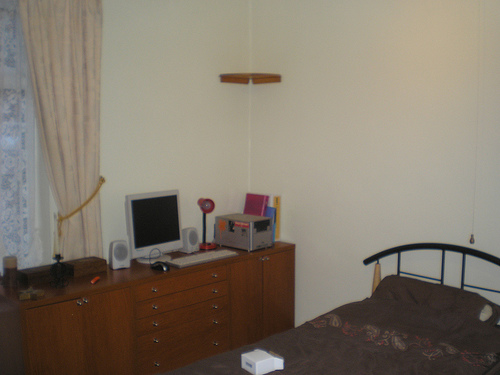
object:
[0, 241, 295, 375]
dresser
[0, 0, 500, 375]
bedroom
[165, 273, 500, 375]
bedspread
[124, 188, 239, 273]
computer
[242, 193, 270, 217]
books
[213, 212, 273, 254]
cassette player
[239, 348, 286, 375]
box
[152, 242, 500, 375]
bed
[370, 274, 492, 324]
pillow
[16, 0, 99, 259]
curtains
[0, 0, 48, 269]
window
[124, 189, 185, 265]
monitor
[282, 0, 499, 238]
wall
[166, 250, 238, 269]
keyboard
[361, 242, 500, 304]
headboard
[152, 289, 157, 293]
knobs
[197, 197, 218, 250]
light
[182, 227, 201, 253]
speaker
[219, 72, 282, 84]
shelf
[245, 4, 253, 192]
corner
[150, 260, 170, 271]
mouse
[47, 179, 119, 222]
cord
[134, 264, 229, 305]
drawers